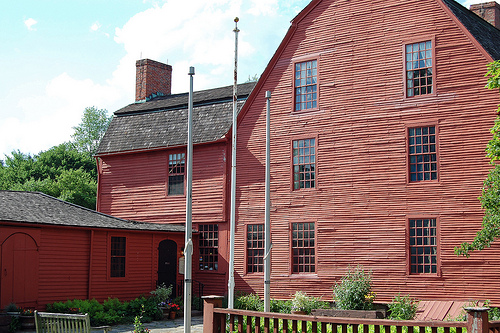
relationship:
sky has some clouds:
[0, 3, 499, 165] [7, 11, 139, 159]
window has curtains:
[402, 33, 437, 99] [405, 44, 432, 95]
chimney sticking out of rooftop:
[132, 56, 173, 101] [100, 75, 259, 146]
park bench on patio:
[31, 305, 108, 332] [2, 302, 204, 332]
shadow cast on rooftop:
[131, 93, 176, 103] [100, 75, 259, 146]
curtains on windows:
[405, 44, 432, 95] [402, 33, 437, 99]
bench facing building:
[31, 305, 108, 332] [2, 1, 499, 322]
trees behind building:
[1, 101, 112, 214] [2, 1, 499, 322]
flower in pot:
[168, 299, 180, 311] [169, 308, 177, 320]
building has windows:
[2, 1, 499, 322] [291, 35, 447, 284]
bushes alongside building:
[223, 263, 417, 325] [2, 1, 499, 322]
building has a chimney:
[2, 1, 499, 322] [132, 56, 173, 101]